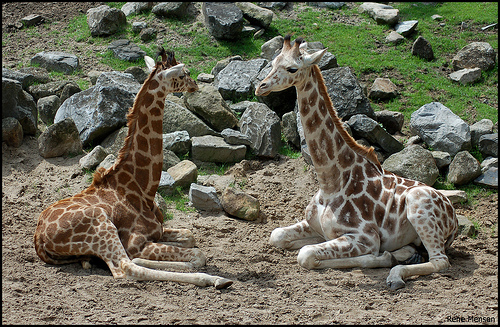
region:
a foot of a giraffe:
[208, 267, 233, 296]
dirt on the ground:
[275, 279, 354, 311]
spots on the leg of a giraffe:
[329, 232, 371, 255]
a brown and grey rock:
[222, 188, 259, 215]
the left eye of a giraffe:
[289, 60, 300, 74]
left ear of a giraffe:
[303, 43, 328, 65]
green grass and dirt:
[420, 82, 465, 97]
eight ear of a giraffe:
[164, 62, 187, 77]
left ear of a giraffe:
[141, 51, 163, 73]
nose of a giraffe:
[188, 77, 201, 91]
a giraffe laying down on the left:
[33, 47, 233, 287]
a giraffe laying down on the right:
[253, 32, 458, 289]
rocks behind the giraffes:
[1, 0, 498, 219]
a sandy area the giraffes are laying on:
[2, 139, 498, 325]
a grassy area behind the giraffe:
[36, 0, 498, 135]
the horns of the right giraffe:
[284, 35, 304, 53]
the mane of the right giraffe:
[311, 61, 383, 163]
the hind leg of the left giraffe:
[41, 200, 233, 287]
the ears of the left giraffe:
[143, 54, 184, 71]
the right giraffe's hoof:
[388, 276, 404, 291]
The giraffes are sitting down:
[25, 39, 498, 275]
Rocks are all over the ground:
[11, 9, 484, 187]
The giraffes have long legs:
[19, 51, 484, 292]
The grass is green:
[285, 0, 497, 110]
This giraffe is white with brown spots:
[262, 50, 492, 265]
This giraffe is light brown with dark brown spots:
[7, 40, 263, 320]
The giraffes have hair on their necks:
[80, 5, 475, 196]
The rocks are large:
[13, 49, 442, 197]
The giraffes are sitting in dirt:
[8, 169, 452, 325]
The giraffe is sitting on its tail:
[24, 158, 219, 324]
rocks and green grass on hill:
[23, 13, 471, 165]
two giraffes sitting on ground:
[33, 33, 480, 310]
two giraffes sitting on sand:
[25, 33, 476, 298]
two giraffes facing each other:
[29, 27, 469, 309]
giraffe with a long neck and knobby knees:
[256, 26, 461, 301]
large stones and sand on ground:
[16, 11, 464, 296]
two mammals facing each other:
[45, 36, 469, 306]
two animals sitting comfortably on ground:
[18, 17, 471, 304]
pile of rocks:
[13, 33, 461, 183]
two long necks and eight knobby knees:
[16, 12, 466, 309]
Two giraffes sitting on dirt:
[16, 38, 469, 288]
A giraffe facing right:
[30, 40, 237, 295]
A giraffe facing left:
[252, 21, 479, 271]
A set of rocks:
[385, 90, 497, 195]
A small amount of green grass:
[313, 5, 491, 135]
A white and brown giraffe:
[251, 11, 468, 292]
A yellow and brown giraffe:
[35, 45, 245, 301]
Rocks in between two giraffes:
[167, 90, 289, 211]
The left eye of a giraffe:
[282, 60, 297, 76]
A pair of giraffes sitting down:
[28, 41, 466, 296]